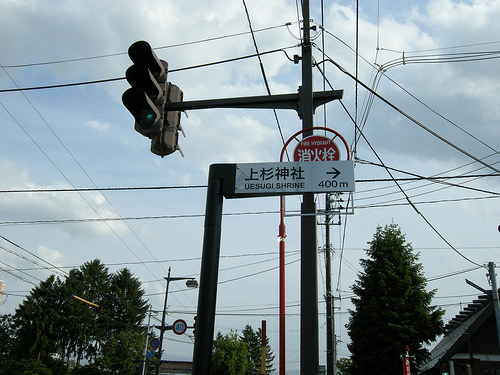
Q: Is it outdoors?
A: Yes, it is outdoors.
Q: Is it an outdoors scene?
A: Yes, it is outdoors.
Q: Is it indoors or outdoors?
A: It is outdoors.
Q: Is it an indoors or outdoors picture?
A: It is outdoors.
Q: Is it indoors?
A: No, it is outdoors.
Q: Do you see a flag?
A: No, there are no flags.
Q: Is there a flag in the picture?
A: No, there are no flags.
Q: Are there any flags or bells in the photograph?
A: No, there are no flags or bells.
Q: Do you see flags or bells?
A: No, there are no flags or bells.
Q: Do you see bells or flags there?
A: No, there are no flags or bells.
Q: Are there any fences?
A: No, there are no fences.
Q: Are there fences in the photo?
A: No, there are no fences.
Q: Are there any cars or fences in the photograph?
A: No, there are no fences or cars.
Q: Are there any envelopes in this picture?
A: No, there are no envelopes.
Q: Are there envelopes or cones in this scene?
A: No, there are no envelopes or cones.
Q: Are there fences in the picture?
A: No, there are no fences.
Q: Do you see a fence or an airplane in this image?
A: No, there are no fences or airplanes.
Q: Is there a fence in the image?
A: No, there are no fences.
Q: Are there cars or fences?
A: No, there are no fences or cars.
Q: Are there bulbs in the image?
A: No, there are no bulbs.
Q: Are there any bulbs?
A: No, there are no bulbs.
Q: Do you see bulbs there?
A: No, there are no bulbs.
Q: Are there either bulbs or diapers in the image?
A: No, there are no bulbs or diapers.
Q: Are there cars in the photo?
A: No, there are no cars.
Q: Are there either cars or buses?
A: No, there are no cars or buses.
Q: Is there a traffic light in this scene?
A: Yes, there is a traffic light.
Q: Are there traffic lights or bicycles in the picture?
A: Yes, there is a traffic light.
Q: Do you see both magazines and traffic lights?
A: No, there is a traffic light but no magazines.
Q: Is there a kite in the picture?
A: No, there are no kites.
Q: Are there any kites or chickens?
A: No, there are no kites or chickens.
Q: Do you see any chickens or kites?
A: No, there are no kites or chickens.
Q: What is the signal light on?
A: The signal light is on the pole.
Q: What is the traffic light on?
A: The signal light is on the pole.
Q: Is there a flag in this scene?
A: No, there are no flags.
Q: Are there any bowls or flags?
A: No, there are no flags or bowls.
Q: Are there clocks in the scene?
A: No, there are no clocks.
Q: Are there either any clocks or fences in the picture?
A: No, there are no clocks or fences.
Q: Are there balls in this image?
A: No, there are no balls.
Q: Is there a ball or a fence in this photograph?
A: No, there are no balls or fences.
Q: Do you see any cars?
A: No, there are no cars.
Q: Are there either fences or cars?
A: No, there are no cars or fences.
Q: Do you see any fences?
A: No, there are no fences.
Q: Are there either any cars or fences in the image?
A: No, there are no fences or cars.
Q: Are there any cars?
A: No, there are no cars.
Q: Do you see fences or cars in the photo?
A: No, there are no cars or fences.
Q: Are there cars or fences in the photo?
A: No, there are no cars or fences.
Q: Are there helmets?
A: No, there are no helmets.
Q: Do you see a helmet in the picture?
A: No, there are no helmets.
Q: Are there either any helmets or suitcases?
A: No, there are no helmets or suitcases.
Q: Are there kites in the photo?
A: No, there are no kites.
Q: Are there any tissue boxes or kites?
A: No, there are no kites or tissue boxes.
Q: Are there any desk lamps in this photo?
A: No, there are no desk lamps.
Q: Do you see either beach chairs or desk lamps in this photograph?
A: No, there are no desk lamps or beach chairs.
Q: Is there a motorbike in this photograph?
A: No, there are no motorcycles.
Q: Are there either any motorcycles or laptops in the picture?
A: No, there are no motorcycles or laptops.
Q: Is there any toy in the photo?
A: No, there are no toys.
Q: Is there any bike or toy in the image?
A: No, there are no toys or bikes.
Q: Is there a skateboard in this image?
A: No, there are no skateboards.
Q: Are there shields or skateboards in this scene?
A: No, there are no skateboards or shields.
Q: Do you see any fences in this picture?
A: No, there are no fences.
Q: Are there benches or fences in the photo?
A: No, there are no fences or benches.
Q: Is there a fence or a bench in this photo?
A: No, there are no fences or benches.